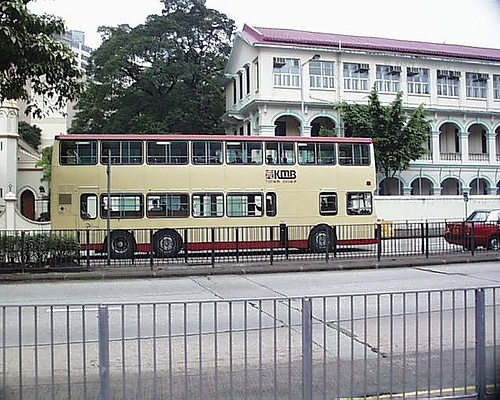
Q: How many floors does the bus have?
A: Two.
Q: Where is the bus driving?
A: On the street.